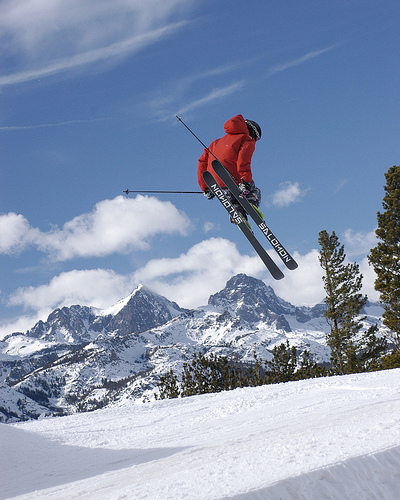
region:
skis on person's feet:
[201, 155, 299, 283]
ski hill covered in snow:
[0, 360, 398, 498]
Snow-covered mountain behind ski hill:
[1, 265, 398, 418]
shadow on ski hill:
[1, 415, 193, 499]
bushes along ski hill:
[153, 344, 337, 397]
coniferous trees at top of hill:
[316, 163, 398, 376]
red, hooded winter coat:
[194, 112, 256, 191]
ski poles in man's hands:
[116, 109, 247, 210]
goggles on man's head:
[244, 117, 261, 140]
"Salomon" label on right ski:
[260, 221, 292, 264]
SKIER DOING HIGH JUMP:
[120, 110, 313, 280]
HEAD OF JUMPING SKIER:
[241, 115, 265, 141]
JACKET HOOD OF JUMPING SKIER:
[222, 112, 249, 134]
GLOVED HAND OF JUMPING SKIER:
[243, 180, 259, 192]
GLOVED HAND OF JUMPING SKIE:
[199, 186, 214, 201]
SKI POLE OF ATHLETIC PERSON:
[117, 186, 201, 198]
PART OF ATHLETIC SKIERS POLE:
[171, 112, 209, 151]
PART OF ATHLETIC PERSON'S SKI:
[249, 208, 310, 273]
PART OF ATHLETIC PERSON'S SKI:
[206, 174, 239, 218]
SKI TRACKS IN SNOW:
[218, 396, 299, 416]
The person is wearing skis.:
[212, 167, 317, 296]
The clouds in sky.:
[40, 195, 208, 274]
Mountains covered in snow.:
[58, 285, 283, 365]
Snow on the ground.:
[79, 394, 316, 482]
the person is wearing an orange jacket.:
[188, 134, 257, 187]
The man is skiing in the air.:
[187, 106, 321, 288]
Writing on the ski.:
[253, 223, 294, 264]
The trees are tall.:
[310, 213, 388, 369]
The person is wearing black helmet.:
[243, 113, 259, 138]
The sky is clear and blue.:
[48, 63, 341, 196]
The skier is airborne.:
[124, 113, 297, 281]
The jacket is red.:
[222, 137, 250, 156]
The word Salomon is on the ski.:
[259, 221, 291, 262]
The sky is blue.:
[326, 55, 398, 129]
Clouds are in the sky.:
[0, 196, 190, 262]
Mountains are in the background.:
[0, 273, 268, 364]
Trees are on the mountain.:
[364, 163, 399, 369]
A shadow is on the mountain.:
[0, 424, 193, 498]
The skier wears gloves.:
[236, 179, 251, 197]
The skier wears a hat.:
[244, 117, 261, 138]